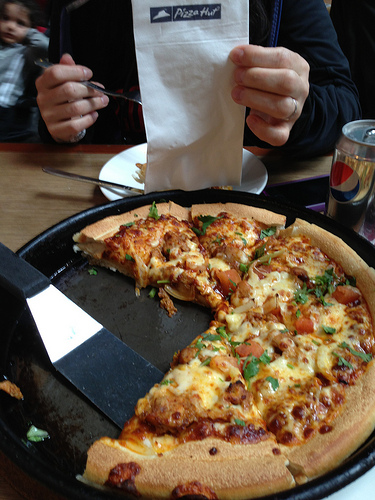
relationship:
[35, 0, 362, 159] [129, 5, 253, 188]
boy holds receipt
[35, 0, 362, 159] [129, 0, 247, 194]
boy holding napkin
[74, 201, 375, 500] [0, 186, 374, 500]
food sitting on pan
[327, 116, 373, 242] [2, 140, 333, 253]
can sitting on table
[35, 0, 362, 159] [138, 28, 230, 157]
boy holding napkin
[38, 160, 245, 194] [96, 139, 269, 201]
siverware resting on plate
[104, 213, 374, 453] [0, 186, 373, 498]
cheese left on platter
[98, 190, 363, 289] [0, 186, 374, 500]
food in pan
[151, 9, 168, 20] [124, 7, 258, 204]
logo on napkin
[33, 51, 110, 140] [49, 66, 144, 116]
hand holding silverware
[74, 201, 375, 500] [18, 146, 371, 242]
food sitting on table